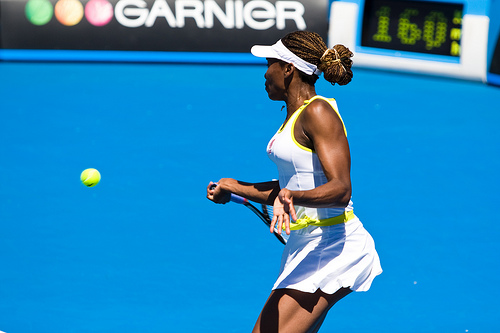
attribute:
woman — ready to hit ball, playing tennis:
[210, 31, 382, 332]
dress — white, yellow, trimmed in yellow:
[261, 96, 385, 297]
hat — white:
[248, 43, 319, 79]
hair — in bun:
[281, 28, 354, 87]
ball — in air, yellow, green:
[80, 168, 100, 188]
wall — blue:
[1, 49, 498, 327]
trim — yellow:
[281, 96, 347, 154]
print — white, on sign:
[112, 0, 308, 29]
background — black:
[1, 3, 330, 53]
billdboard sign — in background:
[3, 2, 328, 66]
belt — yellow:
[286, 210, 357, 232]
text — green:
[365, 5, 462, 54]